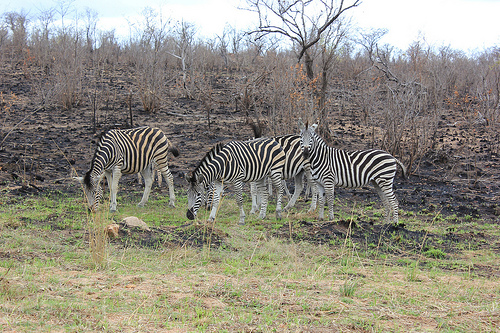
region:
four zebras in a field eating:
[66, 115, 412, 233]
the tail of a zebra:
[394, 156, 411, 184]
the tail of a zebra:
[166, 137, 183, 159]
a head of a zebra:
[292, 115, 322, 161]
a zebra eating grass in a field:
[71, 116, 181, 215]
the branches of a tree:
[241, 0, 361, 62]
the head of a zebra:
[71, 165, 108, 219]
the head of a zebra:
[179, 165, 214, 225]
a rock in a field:
[102, 209, 159, 249]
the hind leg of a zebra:
[371, 170, 406, 228]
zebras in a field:
[76, 114, 407, 238]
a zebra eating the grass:
[70, 116, 184, 216]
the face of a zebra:
[296, 117, 318, 157]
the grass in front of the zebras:
[2, 220, 494, 322]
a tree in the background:
[238, 4, 374, 149]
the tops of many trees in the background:
[11, 11, 496, 78]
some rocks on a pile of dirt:
[104, 215, 154, 240]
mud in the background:
[409, 125, 499, 220]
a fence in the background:
[8, 93, 276, 130]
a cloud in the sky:
[198, 9, 245, 22]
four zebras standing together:
[66, 115, 411, 230]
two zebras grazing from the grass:
[60, 115, 275, 220]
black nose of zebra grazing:
[180, 205, 190, 220]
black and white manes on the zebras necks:
[75, 120, 220, 176]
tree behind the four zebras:
[251, 10, 343, 130]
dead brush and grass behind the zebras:
[10, 29, 465, 200]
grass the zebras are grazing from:
[13, 190, 494, 332]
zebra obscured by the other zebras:
[265, 128, 322, 204]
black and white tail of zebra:
[399, 158, 411, 183]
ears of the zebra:
[295, 117, 318, 132]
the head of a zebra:
[79, 155, 120, 206]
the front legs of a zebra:
[96, 168, 137, 220]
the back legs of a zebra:
[133, 168, 183, 213]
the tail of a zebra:
[159, 134, 191, 160]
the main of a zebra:
[74, 140, 112, 192]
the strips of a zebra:
[181, 100, 376, 208]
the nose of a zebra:
[165, 200, 207, 228]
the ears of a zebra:
[291, 123, 331, 140]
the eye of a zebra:
[188, 185, 210, 210]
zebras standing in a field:
[71, 123, 445, 243]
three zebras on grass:
[90, 104, 398, 236]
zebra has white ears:
[298, 117, 319, 138]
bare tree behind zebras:
[247, 7, 405, 125]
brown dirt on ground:
[140, 210, 440, 282]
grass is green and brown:
[120, 254, 441, 316]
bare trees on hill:
[84, 33, 438, 131]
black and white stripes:
[114, 124, 186, 179]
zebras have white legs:
[184, 180, 281, 205]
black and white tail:
[391, 144, 408, 178]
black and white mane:
[75, 138, 105, 186]